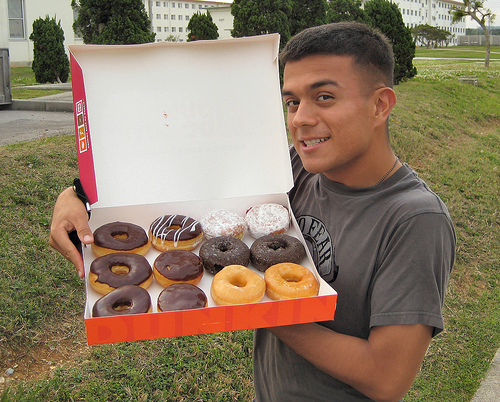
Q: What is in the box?
A: Donuts.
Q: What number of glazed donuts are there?
A: 2.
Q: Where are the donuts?
A: Box.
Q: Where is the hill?
A: Background.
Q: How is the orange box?
A: Open.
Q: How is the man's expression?
A: Smiling.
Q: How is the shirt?
A: Gray.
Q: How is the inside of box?
A: White.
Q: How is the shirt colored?
A: Grey.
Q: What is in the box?
A: Donuts.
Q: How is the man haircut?
A: Short.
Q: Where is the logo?
A: Shirt.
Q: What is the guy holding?
A: Donuts.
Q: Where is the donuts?
A: A box.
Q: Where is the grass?
A: Ground.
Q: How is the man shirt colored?
A: Gray.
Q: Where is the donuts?
A: A box.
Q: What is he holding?
A: A box of donuts.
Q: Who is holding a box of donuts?
A: A teenage boy.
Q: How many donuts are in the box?
A: 12.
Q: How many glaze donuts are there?
A: 2.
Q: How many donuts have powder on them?
A: 2.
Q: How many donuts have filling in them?
A: 2.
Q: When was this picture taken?
A: Daytime.